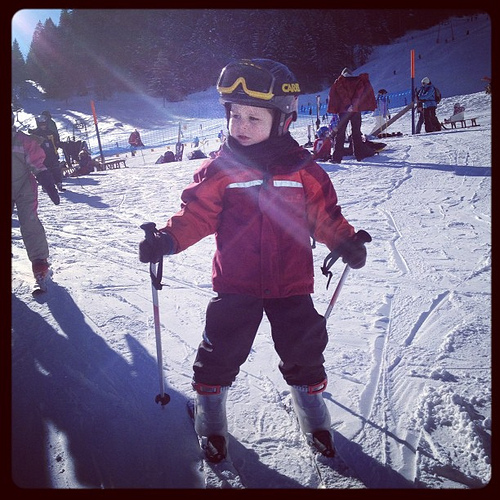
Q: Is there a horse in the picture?
A: No, there are no horses.